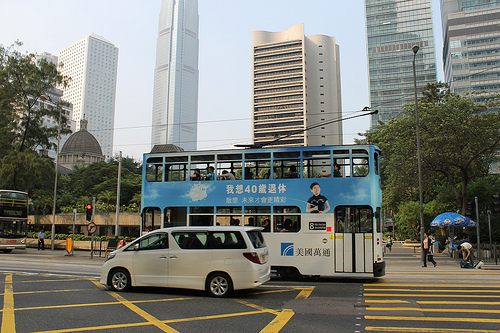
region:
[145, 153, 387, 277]
the bus is double decker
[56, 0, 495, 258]
the buildings are tall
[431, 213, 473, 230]
the umbrella is blue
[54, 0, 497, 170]
the building have windows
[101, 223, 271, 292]
the van is white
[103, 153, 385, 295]
the cars are on the road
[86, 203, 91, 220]
the light is red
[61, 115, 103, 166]
the building has a dome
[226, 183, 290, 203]
the characters on bus are chinese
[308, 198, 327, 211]
the man wears a black shirt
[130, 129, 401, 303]
this is a double decker bus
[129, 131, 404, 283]
the top of the bus is blue & the bottom of the bus is white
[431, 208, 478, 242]
a blue umbrella is in the background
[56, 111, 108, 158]
this building has a dome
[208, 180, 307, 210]
chinese writing is on the side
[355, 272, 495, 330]
yellow stripes are painted on the street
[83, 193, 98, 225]
the stop light is red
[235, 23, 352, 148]
a very tall building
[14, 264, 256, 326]
these stripes are painted on the diagonal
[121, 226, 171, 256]
front window on van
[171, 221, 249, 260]
Back window on van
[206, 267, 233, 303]
back wheel on van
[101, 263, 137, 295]
front wheel on van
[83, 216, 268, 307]
white van next to bus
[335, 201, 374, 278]
double doors on bus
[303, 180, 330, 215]
man picture on bus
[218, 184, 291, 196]
chinese lettering on bus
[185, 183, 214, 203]
white symbol on bus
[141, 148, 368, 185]
top of double decker bus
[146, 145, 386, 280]
a double decker bus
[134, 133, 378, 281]
a blue and white double decker bus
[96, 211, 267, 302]
a car by the bus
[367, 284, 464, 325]
yellow strips on the road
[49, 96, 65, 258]
a metal pole light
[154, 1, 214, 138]
a tall building behind the bus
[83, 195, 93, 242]
a stop light on a sign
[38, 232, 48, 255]
a man on a side walk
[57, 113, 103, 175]
a roof building coming out behind a building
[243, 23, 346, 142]
a white building with windows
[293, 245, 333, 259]
chinese writing on the bus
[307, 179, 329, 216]
chinese boy on the side of the bus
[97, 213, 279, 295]
White Van on the road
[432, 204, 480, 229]
umbrella on the sidewalk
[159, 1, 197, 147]
skycraper on the skyline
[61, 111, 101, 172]
dome building along the road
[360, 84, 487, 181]
tree in front of the building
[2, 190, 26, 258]
back of another bus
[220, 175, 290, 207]
bus number and chinese writing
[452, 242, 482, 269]
man bending over his suitcase